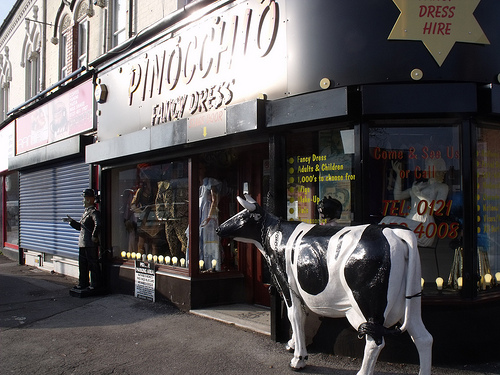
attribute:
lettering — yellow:
[287, 150, 355, 224]